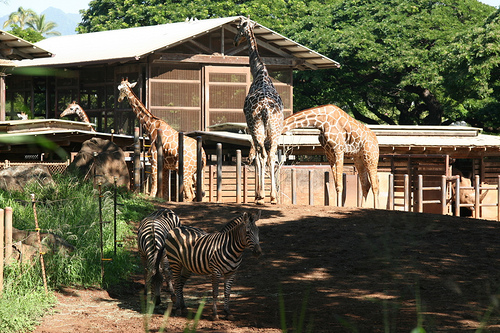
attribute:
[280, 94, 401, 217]
giraffe — tall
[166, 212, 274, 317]
zebra — standing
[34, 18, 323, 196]
building — tall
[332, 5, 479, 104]
trees — large, green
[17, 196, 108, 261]
grass — tall, green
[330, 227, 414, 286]
dirt — large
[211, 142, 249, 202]
post — wood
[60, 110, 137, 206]
rock — brown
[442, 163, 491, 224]
rhinoceros — standing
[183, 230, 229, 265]
fur — black, white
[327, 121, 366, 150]
fur — brown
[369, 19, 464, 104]
leaves — green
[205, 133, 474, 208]
shed — wood, wooden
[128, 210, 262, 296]
zebras — standing